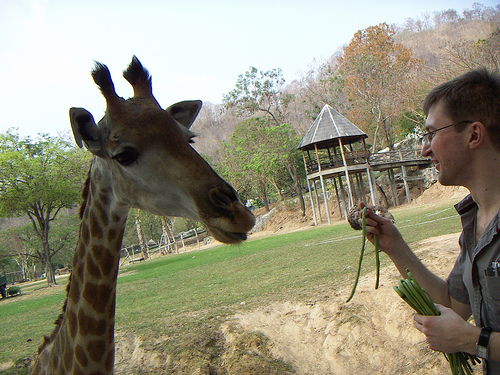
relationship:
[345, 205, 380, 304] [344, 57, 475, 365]
celery held by man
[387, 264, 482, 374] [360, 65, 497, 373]
celery held by man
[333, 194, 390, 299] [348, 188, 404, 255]
plants held by hand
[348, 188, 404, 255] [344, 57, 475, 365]
hand of man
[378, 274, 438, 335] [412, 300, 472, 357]
plants in left hand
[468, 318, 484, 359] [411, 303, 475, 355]
watch on hand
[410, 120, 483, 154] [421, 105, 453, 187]
glasses on face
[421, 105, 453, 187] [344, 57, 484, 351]
face on man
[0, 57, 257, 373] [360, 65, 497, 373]
giraffe next to man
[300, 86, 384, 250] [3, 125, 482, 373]
observation area next to habitat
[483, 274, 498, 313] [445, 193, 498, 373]
pocket on shirt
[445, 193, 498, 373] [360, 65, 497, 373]
shirt of man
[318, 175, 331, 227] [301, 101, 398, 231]
stilt of platform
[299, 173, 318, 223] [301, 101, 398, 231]
stilt of platform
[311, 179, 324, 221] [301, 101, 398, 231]
stilt of platform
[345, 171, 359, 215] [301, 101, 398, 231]
stilt of platform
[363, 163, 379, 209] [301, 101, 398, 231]
stilt of platform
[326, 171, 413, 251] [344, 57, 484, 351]
bird behind man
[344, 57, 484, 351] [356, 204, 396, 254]
man has hand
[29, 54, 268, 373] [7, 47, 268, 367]
neck of giraffe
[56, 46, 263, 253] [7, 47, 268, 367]
head of giraffe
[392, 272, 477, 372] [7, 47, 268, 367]
food to feed giraffe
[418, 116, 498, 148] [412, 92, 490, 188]
eye glasses on face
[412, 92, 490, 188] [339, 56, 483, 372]
face on man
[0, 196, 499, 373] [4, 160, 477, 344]
grass on ground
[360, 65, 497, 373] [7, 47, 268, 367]
man feeding giraffe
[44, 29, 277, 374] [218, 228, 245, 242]
giraffe has tongue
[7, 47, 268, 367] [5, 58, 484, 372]
giraffe at zoo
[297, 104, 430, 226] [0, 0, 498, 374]
gazebo at zoo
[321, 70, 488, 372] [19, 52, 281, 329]
man feeding giraffe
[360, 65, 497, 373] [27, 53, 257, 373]
man staring at giraffe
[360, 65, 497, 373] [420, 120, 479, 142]
man wearing glasses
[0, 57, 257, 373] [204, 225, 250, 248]
giraffe has beard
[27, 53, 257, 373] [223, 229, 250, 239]
giraffe sticking tongue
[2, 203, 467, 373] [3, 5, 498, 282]
grass in background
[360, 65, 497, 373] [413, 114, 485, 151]
man wearing glasses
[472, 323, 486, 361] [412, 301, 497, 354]
watch on arm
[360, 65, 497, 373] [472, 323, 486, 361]
man has watch